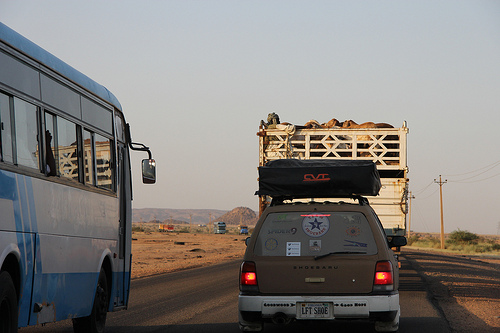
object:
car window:
[249, 209, 381, 259]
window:
[11, 96, 41, 170]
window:
[42, 110, 55, 175]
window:
[57, 116, 80, 182]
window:
[83, 128, 94, 185]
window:
[94, 133, 113, 190]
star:
[309, 218, 323, 231]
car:
[239, 194, 408, 332]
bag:
[258, 158, 383, 194]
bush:
[446, 226, 495, 252]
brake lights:
[373, 269, 392, 285]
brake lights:
[238, 270, 257, 285]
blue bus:
[0, 19, 155, 330]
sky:
[1, 0, 498, 235]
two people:
[430, 170, 453, 249]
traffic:
[243, 157, 400, 319]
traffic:
[265, 117, 406, 234]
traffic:
[0, 26, 158, 331]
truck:
[253, 111, 413, 245]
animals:
[261, 110, 406, 165]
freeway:
[11, 212, 454, 331]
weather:
[2, 1, 497, 330]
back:
[241, 202, 400, 328]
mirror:
[138, 158, 157, 185]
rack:
[254, 154, 382, 205]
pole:
[432, 171, 449, 249]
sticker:
[301, 213, 330, 238]